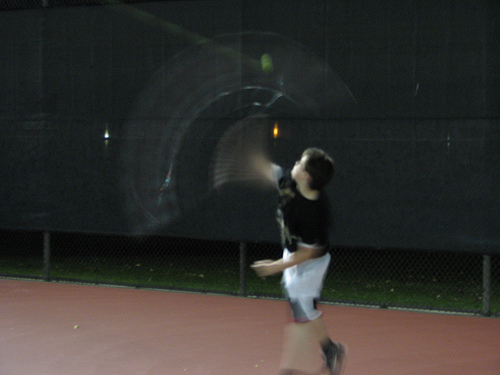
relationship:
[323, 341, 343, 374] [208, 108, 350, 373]
foot of boy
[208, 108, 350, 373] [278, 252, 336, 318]
boy wearing shorts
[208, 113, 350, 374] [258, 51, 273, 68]
boy looks at ball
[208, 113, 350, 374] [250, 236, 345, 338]
boy wearing shorts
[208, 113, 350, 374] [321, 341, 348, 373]
boy has foot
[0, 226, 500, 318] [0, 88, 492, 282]
fence around court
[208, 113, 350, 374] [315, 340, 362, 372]
boy wearing shoes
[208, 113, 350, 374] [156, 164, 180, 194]
boy playing with ball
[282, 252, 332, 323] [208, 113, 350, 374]
shorts on a boy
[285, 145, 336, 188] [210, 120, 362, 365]
head of a player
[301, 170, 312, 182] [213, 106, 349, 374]
ear part of player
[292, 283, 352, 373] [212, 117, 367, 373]
leg of boy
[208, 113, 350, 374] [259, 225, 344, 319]
boy has pants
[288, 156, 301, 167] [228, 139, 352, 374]
nose of player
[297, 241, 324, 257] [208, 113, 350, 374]
elbow of boy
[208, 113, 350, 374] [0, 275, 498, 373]
boy on surface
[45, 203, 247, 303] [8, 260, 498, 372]
fence behind court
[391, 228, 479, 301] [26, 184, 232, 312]
grass other side of fence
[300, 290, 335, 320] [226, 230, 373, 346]
design on shorts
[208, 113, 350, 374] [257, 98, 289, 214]
boy swinging racket